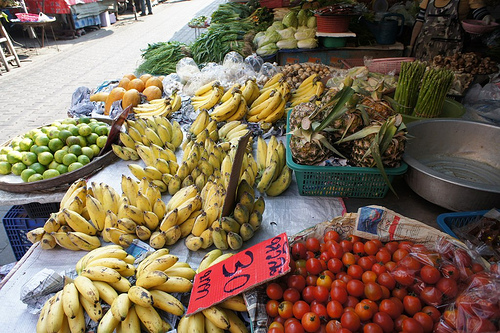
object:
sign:
[180, 228, 291, 318]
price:
[218, 251, 256, 296]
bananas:
[66, 229, 102, 251]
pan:
[400, 115, 498, 217]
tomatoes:
[328, 301, 343, 319]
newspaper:
[243, 203, 491, 333]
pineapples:
[285, 116, 347, 165]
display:
[286, 103, 409, 200]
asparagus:
[393, 60, 426, 117]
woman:
[408, 0, 497, 63]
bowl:
[460, 16, 499, 35]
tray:
[2, 115, 122, 193]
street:
[1, 1, 210, 146]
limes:
[39, 152, 54, 166]